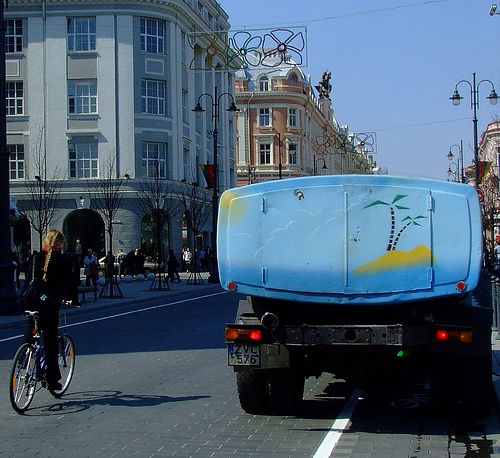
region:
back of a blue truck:
[215, 173, 480, 310]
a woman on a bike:
[7, 229, 86, 411]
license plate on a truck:
[227, 343, 259, 368]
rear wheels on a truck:
[234, 368, 301, 412]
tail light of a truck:
[225, 323, 260, 340]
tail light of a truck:
[433, 325, 473, 343]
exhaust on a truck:
[260, 311, 277, 330]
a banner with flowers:
[185, 24, 309, 73]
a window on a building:
[67, 137, 99, 177]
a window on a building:
[65, 76, 96, 116]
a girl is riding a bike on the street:
[9, 226, 81, 414]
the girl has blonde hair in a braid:
[37, 223, 67, 288]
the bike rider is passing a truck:
[6, 170, 499, 437]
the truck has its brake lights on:
[217, 171, 490, 428]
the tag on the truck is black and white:
[221, 339, 261, 369]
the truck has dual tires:
[232, 342, 318, 417]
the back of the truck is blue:
[217, 171, 484, 307]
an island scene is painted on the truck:
[222, 180, 479, 304]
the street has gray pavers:
[9, 290, 450, 457]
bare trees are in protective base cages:
[12, 121, 216, 337]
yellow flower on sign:
[189, 33, 230, 72]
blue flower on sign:
[224, 29, 261, 68]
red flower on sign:
[262, 29, 302, 63]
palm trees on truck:
[365, 193, 424, 250]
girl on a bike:
[7, 224, 78, 414]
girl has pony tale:
[40, 241, 55, 280]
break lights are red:
[224, 325, 478, 346]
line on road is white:
[299, 388, 374, 456]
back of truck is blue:
[215, 176, 482, 300]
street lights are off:
[190, 93, 240, 122]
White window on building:
[64, 16, 101, 53]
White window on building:
[128, 14, 177, 53]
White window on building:
[140, 69, 174, 118]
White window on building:
[135, 134, 163, 183]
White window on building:
[57, 130, 105, 187]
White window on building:
[56, 74, 116, 116]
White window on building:
[2, 16, 29, 59]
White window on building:
[3, 78, 30, 120]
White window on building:
[9, 139, 31, 173]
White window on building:
[246, 102, 280, 129]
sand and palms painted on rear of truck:
[355, 187, 435, 279]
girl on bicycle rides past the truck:
[8, 222, 78, 412]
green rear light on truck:
[391, 344, 410, 366]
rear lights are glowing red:
[222, 313, 484, 348]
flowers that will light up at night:
[171, 27, 311, 74]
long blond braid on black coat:
[38, 221, 62, 286]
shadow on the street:
[2, 387, 212, 417]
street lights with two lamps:
[444, 72, 498, 188]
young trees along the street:
[28, 150, 216, 296]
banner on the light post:
[196, 159, 227, 194]